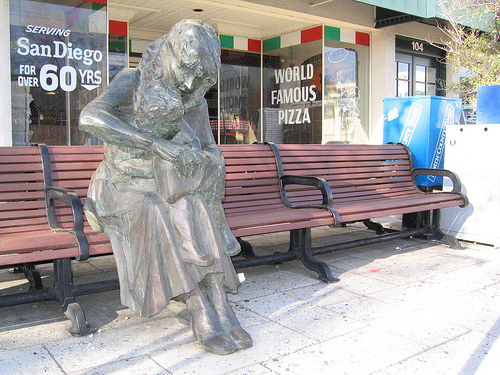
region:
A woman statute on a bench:
[90, 62, 248, 317]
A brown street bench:
[280, 144, 465, 221]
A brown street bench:
[212, 135, 311, 234]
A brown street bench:
[5, 146, 117, 259]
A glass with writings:
[18, 19, 107, 116]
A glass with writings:
[265, 46, 319, 140]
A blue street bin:
[377, 78, 460, 185]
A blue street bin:
[470, 76, 498, 111]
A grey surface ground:
[362, 246, 462, 353]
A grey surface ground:
[249, 269, 307, 374]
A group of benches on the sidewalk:
[6, 135, 470, 338]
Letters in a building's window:
[268, 62, 317, 126]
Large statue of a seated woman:
[80, 17, 254, 354]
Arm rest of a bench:
[276, 170, 336, 209]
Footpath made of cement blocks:
[275, 288, 495, 372]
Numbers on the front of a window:
[38, 62, 78, 94]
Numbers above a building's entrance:
[411, 42, 423, 50]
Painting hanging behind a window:
[300, 48, 359, 102]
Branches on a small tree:
[431, 0, 498, 97]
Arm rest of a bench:
[46, 185, 84, 233]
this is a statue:
[92, 35, 242, 314]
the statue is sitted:
[94, 11, 243, 313]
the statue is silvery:
[87, 30, 244, 313]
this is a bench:
[307, 145, 396, 217]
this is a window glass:
[285, 53, 349, 114]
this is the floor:
[296, 285, 402, 370]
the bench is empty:
[337, 139, 392, 191]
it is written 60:
[35, 65, 85, 92]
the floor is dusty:
[101, 319, 170, 368]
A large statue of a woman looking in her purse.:
[77, 20, 253, 353]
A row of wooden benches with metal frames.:
[0, 142, 467, 335]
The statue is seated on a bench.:
[29, 17, 340, 354]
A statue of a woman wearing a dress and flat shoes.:
[77, 20, 252, 353]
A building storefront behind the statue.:
[0, 0, 499, 145]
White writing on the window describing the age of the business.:
[15, 23, 101, 91]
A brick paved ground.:
[0, 217, 499, 373]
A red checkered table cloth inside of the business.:
[217, 117, 252, 128]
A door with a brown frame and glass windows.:
[395, 35, 445, 96]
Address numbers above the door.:
[409, 39, 426, 54]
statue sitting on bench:
[94, 49, 281, 327]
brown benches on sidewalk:
[1, 131, 441, 256]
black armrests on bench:
[424, 155, 461, 221]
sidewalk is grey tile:
[322, 258, 436, 354]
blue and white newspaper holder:
[377, 110, 442, 184]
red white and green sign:
[108, 27, 382, 91]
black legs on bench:
[33, 274, 80, 330]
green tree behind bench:
[422, 20, 482, 115]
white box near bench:
[426, 125, 493, 241]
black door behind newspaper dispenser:
[393, 33, 452, 109]